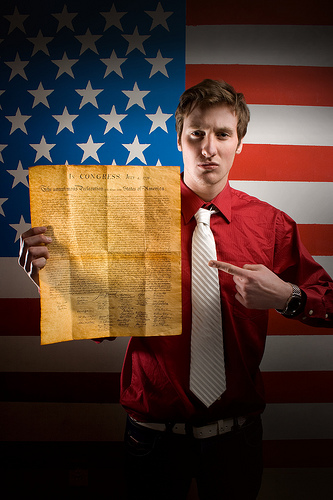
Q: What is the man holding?
A: A paper.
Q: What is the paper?
A: The declaration of independence.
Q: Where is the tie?
A: On the man's neck.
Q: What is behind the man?
A: The US flag.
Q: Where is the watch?
A: On the man's wrist.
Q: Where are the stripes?
A: On the flag.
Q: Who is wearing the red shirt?
A: The man.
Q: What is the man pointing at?
A: The paper.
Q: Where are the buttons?
A: On the shirt.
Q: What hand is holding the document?
A: The right hand.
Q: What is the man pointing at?
A: The document.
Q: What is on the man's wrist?
A: A watch.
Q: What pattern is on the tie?
A: Stripes.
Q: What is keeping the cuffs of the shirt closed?
A: White buttons.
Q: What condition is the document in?
A: Its weathered.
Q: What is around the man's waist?
A: A white belt.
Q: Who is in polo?
A: A man.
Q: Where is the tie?
A: On shirt.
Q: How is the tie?
A: Striped.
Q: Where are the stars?
A: On flag.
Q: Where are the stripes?
A: On flag.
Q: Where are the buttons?
A: On shirt.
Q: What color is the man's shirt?
A: Red.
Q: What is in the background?
A: American flag.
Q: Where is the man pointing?
A: At the paper.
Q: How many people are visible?
A: One.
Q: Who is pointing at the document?
A: The man.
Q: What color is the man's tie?
A: White.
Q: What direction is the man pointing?
A: Left.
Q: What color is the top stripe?
A: Red.